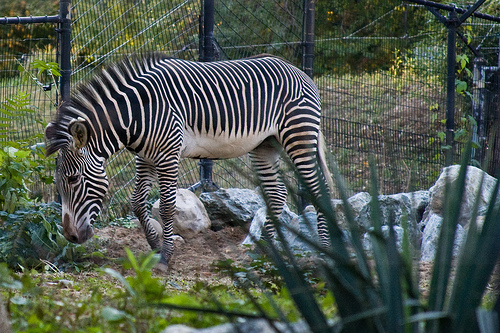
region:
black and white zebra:
[29, 43, 343, 264]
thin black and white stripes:
[151, 53, 297, 138]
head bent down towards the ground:
[28, 111, 137, 240]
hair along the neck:
[37, 46, 168, 153]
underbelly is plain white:
[185, 134, 275, 157]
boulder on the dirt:
[152, 181, 205, 236]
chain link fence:
[1, 5, 499, 210]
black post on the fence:
[184, 3, 223, 193]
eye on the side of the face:
[69, 170, 83, 187]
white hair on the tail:
[314, 128, 346, 190]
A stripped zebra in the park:
[45, 59, 335, 269]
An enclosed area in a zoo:
[0, 0, 498, 230]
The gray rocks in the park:
[154, 162, 497, 258]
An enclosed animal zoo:
[0, 0, 497, 332]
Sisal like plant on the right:
[164, 145, 498, 331]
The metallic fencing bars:
[1, 0, 498, 196]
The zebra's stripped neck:
[40, 52, 167, 154]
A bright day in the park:
[1, 0, 498, 332]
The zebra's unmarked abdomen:
[180, 126, 293, 161]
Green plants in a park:
[0, 0, 497, 331]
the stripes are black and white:
[33, 60, 345, 240]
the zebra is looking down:
[27, 83, 197, 254]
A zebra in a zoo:
[50, 54, 366, 259]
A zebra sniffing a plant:
[49, 36, 369, 269]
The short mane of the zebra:
[57, 39, 174, 116]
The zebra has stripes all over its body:
[33, 43, 348, 253]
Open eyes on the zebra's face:
[50, 167, 88, 192]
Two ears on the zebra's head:
[32, 113, 102, 154]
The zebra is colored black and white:
[40, 41, 358, 268]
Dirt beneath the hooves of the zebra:
[102, 223, 186, 276]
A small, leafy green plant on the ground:
[0, 203, 107, 278]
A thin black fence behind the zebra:
[0, 5, 471, 180]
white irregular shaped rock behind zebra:
[150, 189, 210, 234]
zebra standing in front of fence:
[36, 53, 349, 270]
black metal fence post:
[57, 0, 76, 104]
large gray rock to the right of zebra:
[419, 162, 497, 276]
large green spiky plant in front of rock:
[141, 124, 496, 330]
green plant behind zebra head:
[4, 202, 99, 268]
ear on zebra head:
[66, 115, 90, 143]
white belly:
[176, 132, 271, 157]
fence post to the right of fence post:
[200, 2, 219, 61]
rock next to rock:
[203, 185, 265, 229]